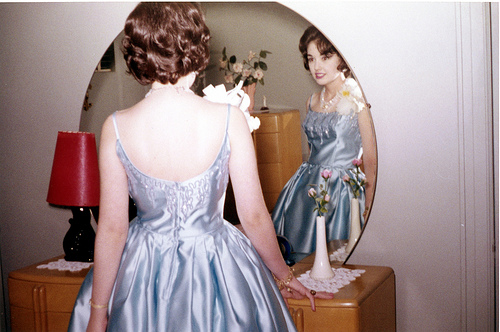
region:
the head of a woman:
[112, 2, 214, 89]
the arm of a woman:
[221, 103, 293, 278]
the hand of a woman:
[276, 272, 332, 313]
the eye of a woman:
[318, 50, 335, 65]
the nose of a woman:
[311, 55, 326, 74]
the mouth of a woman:
[309, 70, 330, 82]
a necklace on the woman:
[315, 72, 355, 113]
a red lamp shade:
[40, 125, 104, 216]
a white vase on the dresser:
[303, 210, 341, 283]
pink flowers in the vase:
[304, 165, 336, 213]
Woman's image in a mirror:
[262, 17, 377, 264]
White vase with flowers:
[304, 166, 348, 289]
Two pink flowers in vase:
[308, 166, 333, 211]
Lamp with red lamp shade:
[45, 118, 104, 268]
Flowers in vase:
[219, 44, 264, 115]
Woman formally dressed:
[79, 1, 311, 331]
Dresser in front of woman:
[10, 251, 400, 330]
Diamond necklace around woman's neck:
[312, 81, 347, 108]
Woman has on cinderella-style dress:
[270, 95, 363, 242]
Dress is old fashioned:
[267, 81, 366, 249]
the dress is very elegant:
[139, 253, 212, 293]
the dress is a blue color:
[164, 265, 206, 304]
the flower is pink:
[314, 161, 338, 183]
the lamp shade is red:
[46, 120, 96, 200]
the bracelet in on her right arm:
[276, 272, 317, 293]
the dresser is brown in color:
[26, 285, 57, 306]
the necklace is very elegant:
[311, 80, 345, 112]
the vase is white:
[313, 218, 337, 265]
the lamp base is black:
[58, 225, 97, 262]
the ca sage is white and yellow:
[333, 75, 368, 124]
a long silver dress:
[63, 92, 295, 329]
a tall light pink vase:
[309, 214, 334, 279]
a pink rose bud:
[320, 167, 332, 182]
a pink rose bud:
[305, 184, 316, 197]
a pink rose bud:
[322, 193, 330, 201]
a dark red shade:
[44, 128, 101, 209]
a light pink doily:
[290, 262, 362, 292]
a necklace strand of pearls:
[314, 84, 341, 110]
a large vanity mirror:
[73, 4, 380, 267]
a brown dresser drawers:
[6, 258, 407, 329]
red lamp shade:
[39, 116, 103, 223]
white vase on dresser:
[310, 212, 337, 284]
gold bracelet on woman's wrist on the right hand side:
[270, 266, 307, 300]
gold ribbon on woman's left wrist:
[79, 293, 116, 320]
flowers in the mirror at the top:
[217, 42, 282, 97]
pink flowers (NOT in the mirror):
[312, 167, 337, 211]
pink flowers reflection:
[345, 151, 371, 189]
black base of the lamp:
[62, 207, 99, 267]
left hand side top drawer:
[15, 275, 85, 315]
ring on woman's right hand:
[305, 278, 329, 301]